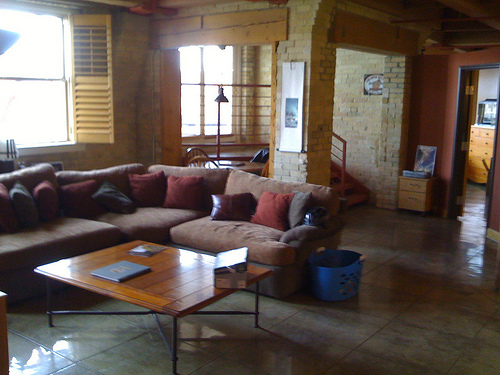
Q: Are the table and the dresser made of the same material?
A: Yes, both the table and the dresser are made of wood.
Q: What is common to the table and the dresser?
A: The material, both the table and the dresser are wooden.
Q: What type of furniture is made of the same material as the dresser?
A: The table is made of the same material as the dresser.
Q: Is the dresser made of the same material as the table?
A: Yes, both the dresser and the table are made of wood.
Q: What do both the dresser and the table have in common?
A: The material, both the dresser and the table are wooden.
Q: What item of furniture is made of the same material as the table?
A: The dresser is made of the same material as the table.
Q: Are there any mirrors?
A: No, there are no mirrors.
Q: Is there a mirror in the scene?
A: No, there are no mirrors.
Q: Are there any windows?
A: Yes, there is a window.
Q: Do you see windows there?
A: Yes, there is a window.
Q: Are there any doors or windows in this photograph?
A: Yes, there is a window.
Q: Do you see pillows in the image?
A: Yes, there is a pillow.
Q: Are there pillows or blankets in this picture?
A: Yes, there is a pillow.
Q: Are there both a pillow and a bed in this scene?
A: No, there is a pillow but no beds.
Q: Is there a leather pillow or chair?
A: Yes, there is a leather pillow.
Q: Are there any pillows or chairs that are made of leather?
A: Yes, the pillow is made of leather.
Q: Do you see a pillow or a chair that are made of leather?
A: Yes, the pillow is made of leather.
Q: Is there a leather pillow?
A: Yes, there is a pillow that is made of leather.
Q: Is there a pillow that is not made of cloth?
A: Yes, there is a pillow that is made of leather.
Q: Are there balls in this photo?
A: No, there are no balls.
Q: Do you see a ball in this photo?
A: No, there are no balls.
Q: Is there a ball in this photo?
A: No, there are no balls.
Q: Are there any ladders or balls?
A: No, there are no balls or ladders.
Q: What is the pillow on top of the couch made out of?
A: The pillow is made of leather.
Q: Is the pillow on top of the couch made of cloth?
A: No, the pillow is made of leather.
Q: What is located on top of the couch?
A: The pillow is on top of the couch.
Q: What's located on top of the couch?
A: The pillow is on top of the couch.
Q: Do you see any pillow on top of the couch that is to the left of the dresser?
A: Yes, there is a pillow on top of the couch.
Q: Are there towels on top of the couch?
A: No, there is a pillow on top of the couch.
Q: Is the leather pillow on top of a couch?
A: Yes, the pillow is on top of a couch.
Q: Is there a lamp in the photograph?
A: Yes, there is a lamp.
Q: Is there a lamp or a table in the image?
A: Yes, there is a lamp.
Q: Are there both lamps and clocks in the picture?
A: No, there is a lamp but no clocks.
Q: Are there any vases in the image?
A: No, there are no vases.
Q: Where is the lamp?
A: The lamp is on the floor.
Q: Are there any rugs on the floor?
A: No, there is a lamp on the floor.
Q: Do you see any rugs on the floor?
A: No, there is a lamp on the floor.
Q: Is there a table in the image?
A: Yes, there is a table.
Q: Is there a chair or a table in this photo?
A: Yes, there is a table.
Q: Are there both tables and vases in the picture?
A: No, there is a table but no vases.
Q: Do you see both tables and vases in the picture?
A: No, there is a table but no vases.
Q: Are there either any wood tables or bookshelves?
A: Yes, there is a wood table.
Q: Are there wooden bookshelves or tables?
A: Yes, there is a wood table.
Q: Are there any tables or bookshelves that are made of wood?
A: Yes, the table is made of wood.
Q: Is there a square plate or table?
A: Yes, there is a square table.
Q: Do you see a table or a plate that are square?
A: Yes, the table is square.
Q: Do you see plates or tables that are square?
A: Yes, the table is square.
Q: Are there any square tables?
A: Yes, there is a square table.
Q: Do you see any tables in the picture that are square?
A: Yes, there is a table that is square.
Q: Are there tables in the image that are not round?
A: Yes, there is a square table.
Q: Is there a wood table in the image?
A: Yes, there is a wood table.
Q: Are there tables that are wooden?
A: Yes, there is a table that is wooden.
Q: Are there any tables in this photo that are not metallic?
A: Yes, there is a wooden table.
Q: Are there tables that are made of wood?
A: Yes, there is a table that is made of wood.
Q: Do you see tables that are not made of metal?
A: Yes, there is a table that is made of wood.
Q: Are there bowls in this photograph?
A: No, there are no bowls.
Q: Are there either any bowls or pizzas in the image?
A: No, there are no bowls or pizzas.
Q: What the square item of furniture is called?
A: The piece of furniture is a table.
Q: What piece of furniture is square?
A: The piece of furniture is a table.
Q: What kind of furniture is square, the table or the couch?
A: The table is square.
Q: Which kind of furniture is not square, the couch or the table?
A: The couch is not square.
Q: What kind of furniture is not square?
A: The furniture is a couch.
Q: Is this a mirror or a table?
A: This is a table.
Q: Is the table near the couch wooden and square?
A: Yes, the table is wooden and square.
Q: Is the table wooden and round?
A: No, the table is wooden but square.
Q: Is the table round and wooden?
A: No, the table is wooden but square.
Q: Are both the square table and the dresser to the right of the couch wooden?
A: Yes, both the table and the dresser are wooden.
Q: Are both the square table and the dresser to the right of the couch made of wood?
A: Yes, both the table and the dresser are made of wood.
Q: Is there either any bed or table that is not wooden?
A: No, there is a table but it is wooden.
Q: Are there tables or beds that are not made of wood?
A: No, there is a table but it is made of wood.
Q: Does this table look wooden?
A: Yes, the table is wooden.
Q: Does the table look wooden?
A: Yes, the table is wooden.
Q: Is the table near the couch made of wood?
A: Yes, the table is made of wood.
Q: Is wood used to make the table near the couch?
A: Yes, the table is made of wood.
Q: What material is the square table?
A: The table is made of wood.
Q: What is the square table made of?
A: The table is made of wood.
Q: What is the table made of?
A: The table is made of wood.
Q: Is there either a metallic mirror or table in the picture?
A: No, there is a table but it is wooden.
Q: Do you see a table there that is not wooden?
A: No, there is a table but it is wooden.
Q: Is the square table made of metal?
A: No, the table is made of wood.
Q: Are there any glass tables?
A: No, there is a table but it is made of wood.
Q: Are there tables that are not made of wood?
A: No, there is a table but it is made of wood.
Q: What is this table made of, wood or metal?
A: The table is made of wood.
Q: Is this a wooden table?
A: Yes, this is a wooden table.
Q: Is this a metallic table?
A: No, this is a wooden table.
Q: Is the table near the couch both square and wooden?
A: Yes, the table is square and wooden.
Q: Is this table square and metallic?
A: No, the table is square but wooden.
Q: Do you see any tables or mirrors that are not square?
A: No, there is a table but it is square.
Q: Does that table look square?
A: Yes, the table is square.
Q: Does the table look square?
A: Yes, the table is square.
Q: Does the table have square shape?
A: Yes, the table is square.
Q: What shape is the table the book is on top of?
A: The table is square.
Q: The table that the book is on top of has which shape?
A: The table is square.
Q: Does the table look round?
A: No, the table is square.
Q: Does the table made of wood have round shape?
A: No, the table is square.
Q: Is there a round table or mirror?
A: No, there is a table but it is square.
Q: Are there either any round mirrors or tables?
A: No, there is a table but it is square.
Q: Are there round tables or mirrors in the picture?
A: No, there is a table but it is square.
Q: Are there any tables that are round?
A: No, there is a table but it is square.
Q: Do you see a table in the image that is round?
A: No, there is a table but it is square.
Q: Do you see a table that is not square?
A: No, there is a table but it is square.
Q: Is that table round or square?
A: The table is square.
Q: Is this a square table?
A: Yes, this is a square table.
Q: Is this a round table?
A: No, this is a square table.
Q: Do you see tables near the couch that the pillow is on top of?
A: Yes, there is a table near the couch.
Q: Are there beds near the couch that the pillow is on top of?
A: No, there is a table near the couch.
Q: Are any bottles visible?
A: No, there are no bottles.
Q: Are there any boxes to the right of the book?
A: Yes, there is a box to the right of the book.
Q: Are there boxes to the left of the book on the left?
A: No, the box is to the right of the book.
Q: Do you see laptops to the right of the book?
A: No, there is a box to the right of the book.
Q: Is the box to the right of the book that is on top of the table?
A: Yes, the box is to the right of the book.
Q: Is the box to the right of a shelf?
A: No, the box is to the right of the book.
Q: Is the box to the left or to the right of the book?
A: The box is to the right of the book.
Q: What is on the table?
A: The box is on the table.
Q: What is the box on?
A: The box is on the table.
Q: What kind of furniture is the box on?
A: The box is on the table.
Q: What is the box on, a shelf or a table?
A: The box is on a table.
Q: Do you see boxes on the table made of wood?
A: Yes, there is a box on the table.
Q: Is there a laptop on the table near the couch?
A: No, there is a box on the table.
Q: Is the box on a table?
A: Yes, the box is on a table.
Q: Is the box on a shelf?
A: No, the box is on a table.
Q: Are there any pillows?
A: Yes, there is a pillow.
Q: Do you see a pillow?
A: Yes, there is a pillow.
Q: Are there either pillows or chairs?
A: Yes, there is a pillow.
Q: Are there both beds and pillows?
A: No, there is a pillow but no beds.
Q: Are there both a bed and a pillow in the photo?
A: No, there is a pillow but no beds.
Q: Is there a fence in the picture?
A: No, there are no fences.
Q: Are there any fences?
A: No, there are no fences.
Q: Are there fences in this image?
A: No, there are no fences.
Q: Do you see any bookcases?
A: No, there are no bookcases.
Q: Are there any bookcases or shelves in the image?
A: No, there are no bookcases or shelves.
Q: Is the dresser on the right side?
A: Yes, the dresser is on the right of the image.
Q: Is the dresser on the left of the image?
A: No, the dresser is on the right of the image.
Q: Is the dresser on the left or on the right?
A: The dresser is on the right of the image.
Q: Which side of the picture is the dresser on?
A: The dresser is on the right of the image.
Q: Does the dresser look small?
A: Yes, the dresser is small.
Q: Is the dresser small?
A: Yes, the dresser is small.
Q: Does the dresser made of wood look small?
A: Yes, the dresser is small.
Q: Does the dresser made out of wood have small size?
A: Yes, the dresser is small.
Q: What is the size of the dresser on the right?
A: The dresser is small.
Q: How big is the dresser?
A: The dresser is small.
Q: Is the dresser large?
A: No, the dresser is small.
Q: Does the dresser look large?
A: No, the dresser is small.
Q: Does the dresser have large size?
A: No, the dresser is small.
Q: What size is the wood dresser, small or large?
A: The dresser is small.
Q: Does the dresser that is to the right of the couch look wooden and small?
A: Yes, the dresser is wooden and small.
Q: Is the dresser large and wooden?
A: No, the dresser is wooden but small.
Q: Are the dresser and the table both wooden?
A: Yes, both the dresser and the table are wooden.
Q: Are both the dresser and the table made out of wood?
A: Yes, both the dresser and the table are made of wood.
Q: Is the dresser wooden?
A: Yes, the dresser is wooden.